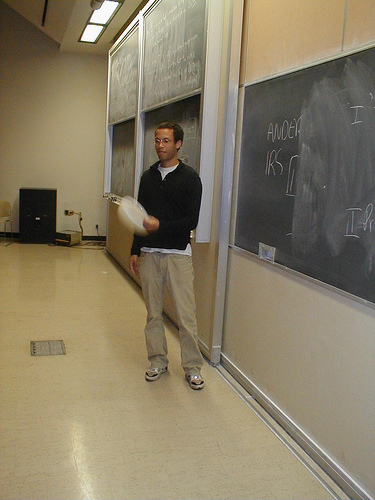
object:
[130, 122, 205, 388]
man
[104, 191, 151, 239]
frisbee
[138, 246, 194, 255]
tee shirt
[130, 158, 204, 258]
sweater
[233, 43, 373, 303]
blackboard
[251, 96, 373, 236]
chalk writing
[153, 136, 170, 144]
glasses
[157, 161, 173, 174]
tee shirt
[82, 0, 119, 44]
lights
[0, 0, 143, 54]
ceiling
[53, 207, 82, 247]
projector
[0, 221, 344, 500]
floor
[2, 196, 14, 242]
chair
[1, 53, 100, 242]
wall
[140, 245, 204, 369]
pants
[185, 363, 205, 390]
shoes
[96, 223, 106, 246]
speaker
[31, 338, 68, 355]
vent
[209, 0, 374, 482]
wall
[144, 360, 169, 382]
shoes